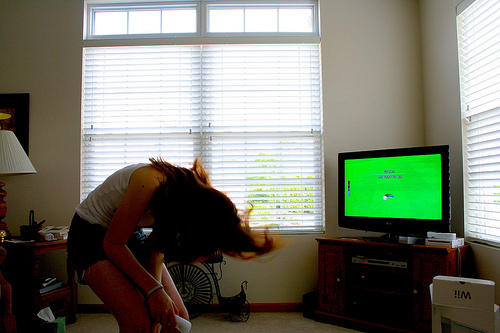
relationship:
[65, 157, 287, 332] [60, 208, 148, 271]
girl wearing shorts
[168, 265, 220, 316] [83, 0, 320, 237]
fan under window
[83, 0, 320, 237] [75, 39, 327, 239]
window covered with blinds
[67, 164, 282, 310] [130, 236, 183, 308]
girl wearing bracelet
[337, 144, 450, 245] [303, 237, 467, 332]
television on stand